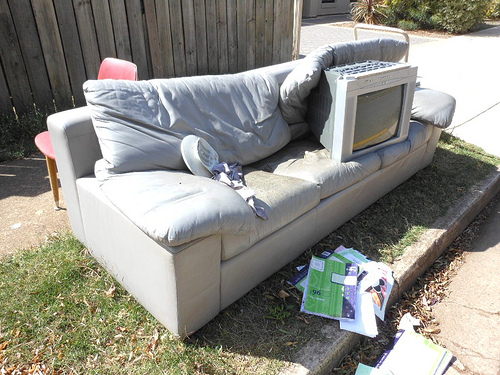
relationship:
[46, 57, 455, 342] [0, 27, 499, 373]
couch on street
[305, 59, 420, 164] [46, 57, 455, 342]
television on couch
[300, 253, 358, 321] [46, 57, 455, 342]
paper next to couch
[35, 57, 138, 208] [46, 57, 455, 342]
chair behind couch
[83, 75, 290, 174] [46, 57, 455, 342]
pillow on couch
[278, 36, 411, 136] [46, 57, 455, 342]
pillow on couch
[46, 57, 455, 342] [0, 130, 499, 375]
couch sitting on grass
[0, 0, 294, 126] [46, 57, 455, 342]
fence behind couch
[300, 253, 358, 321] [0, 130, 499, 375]
paper sitting on grass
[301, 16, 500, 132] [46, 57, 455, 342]
driveway next to couch